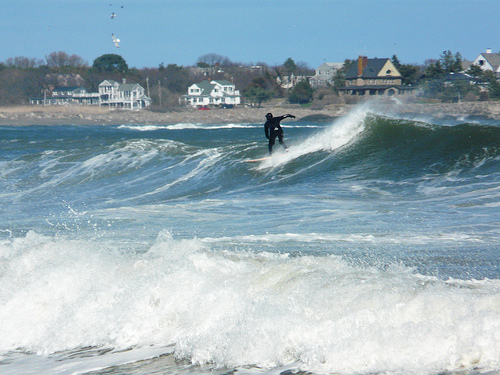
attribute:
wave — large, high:
[20, 99, 500, 204]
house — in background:
[177, 72, 244, 109]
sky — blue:
[2, 2, 500, 67]